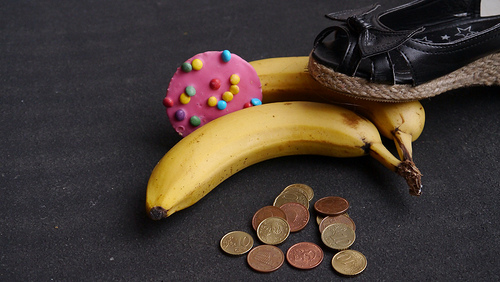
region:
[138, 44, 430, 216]
Two bananas on a counter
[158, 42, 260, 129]
A pink cookie with candies on it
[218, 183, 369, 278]
Money laying on the counter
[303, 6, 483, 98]
A black shoe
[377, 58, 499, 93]
A black shoe with fabric trim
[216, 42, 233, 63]
A aqua colored decoration on cookie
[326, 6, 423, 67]
A black bow on black shoe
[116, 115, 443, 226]
A banana with black bottom piece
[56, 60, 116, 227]
A dark gray counter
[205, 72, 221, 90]
A red candy decoration on pink cookie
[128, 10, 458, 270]
collection of diverse items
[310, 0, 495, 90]
black shoe with straw heel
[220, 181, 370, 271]
coins on a black background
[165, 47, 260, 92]
half a cupcake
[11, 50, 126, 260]
black felt cover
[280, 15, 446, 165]
two yellow bananas with a shoe on top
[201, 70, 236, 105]
sprinkles on top of frosting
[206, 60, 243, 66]
cupcake's pink frosting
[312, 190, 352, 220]
coin leaned on top of another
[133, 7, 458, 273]
four things in one picture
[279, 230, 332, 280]
copper colored coin on table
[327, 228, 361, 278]
two gold colored coins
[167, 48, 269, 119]
pink cookie with sprinkles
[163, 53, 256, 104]
small yellow red and blue dots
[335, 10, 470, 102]
black and brown shoes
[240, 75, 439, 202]
two yellow bananas on stems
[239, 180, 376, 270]
pile of coins on table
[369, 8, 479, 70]
white stars inside of shoes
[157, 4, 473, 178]
shoe cookie and bananas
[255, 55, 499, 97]
brown braided bottom of shoe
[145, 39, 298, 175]
bananas and a pink cookie with candy topping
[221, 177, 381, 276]
a pile of pennies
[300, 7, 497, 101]
a black shoe on top of a banana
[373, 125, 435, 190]
the stems of bananas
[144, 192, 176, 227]
the tip of a banana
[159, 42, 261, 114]
a pink cookies with candy toppings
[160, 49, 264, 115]
blue, red, and yellow candy on top of a pink cookie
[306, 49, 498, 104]
the brown sole of a black shoe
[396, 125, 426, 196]
a stem of a banana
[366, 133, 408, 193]
a stem of a banana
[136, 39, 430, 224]
two bananas on a table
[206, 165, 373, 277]
coins on black a table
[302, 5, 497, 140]
a black shoe over a banana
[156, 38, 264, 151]
a pink cookie sprinkles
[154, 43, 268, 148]
sprinkles color yellow, blue, red, green and purple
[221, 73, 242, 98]
yellow sprinkles on cookie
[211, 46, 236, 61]
blue sprinkle on cookie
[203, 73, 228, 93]
red sprinkle on cookie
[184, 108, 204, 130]
green sprinkle on cookie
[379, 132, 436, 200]
stems of two bananas